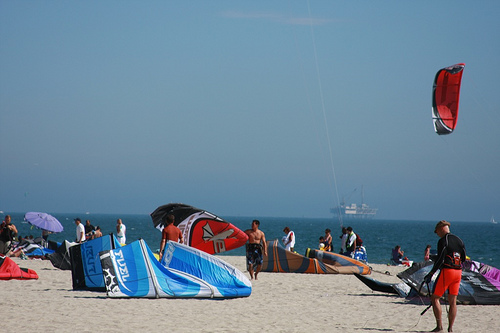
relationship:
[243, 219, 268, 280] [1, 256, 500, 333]
man on beach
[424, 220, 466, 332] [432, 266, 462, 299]
man wearing shorts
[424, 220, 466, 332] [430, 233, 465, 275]
man wearing tee shirt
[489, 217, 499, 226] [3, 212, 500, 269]
boat on ocean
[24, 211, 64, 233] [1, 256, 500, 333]
umbrella on beach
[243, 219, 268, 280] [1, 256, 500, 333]
man walking forward on beach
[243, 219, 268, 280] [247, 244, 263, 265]
man wearing shorts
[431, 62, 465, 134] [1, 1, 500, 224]
kite floating in sky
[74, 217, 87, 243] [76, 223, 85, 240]
man wearing tee shirt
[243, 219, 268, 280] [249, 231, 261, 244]
man has chest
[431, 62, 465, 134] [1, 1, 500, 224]
kite in sky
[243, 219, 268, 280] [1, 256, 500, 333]
man at beach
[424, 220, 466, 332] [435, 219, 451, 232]
man wearing cap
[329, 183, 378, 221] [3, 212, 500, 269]
oil rig in ocean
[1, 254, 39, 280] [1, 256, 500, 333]
kite on beach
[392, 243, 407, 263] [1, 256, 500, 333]
person on beach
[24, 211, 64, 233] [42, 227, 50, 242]
umbrella over person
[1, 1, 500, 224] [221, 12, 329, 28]
sky has cloud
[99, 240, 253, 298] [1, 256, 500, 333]
kite on beach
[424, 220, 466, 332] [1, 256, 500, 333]
man on beach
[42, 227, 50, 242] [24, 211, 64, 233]
person under umbrella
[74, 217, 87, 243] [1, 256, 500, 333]
man on beach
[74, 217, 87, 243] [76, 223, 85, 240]
man in tee shirt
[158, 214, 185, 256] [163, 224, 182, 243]
man wearing tee shirt